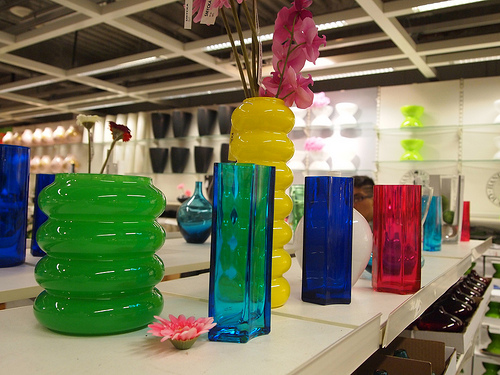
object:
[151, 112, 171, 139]
vase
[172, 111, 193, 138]
vase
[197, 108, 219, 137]
vase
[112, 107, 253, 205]
wall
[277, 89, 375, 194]
wall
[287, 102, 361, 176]
vases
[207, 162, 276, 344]
glass vase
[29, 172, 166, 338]
vase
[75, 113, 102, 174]
flower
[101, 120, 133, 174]
flower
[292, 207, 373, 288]
vase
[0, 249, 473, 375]
counter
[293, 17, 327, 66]
flower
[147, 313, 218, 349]
flower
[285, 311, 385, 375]
shelf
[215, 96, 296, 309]
vase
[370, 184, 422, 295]
vase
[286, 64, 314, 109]
flower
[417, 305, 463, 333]
light bulb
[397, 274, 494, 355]
drawer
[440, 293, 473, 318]
light bulb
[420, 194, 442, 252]
vase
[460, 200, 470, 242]
vase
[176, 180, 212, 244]
vase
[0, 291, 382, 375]
table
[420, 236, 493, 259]
table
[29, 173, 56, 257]
vase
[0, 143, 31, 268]
vase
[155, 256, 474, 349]
table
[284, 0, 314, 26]
flower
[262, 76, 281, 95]
flower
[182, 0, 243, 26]
flower